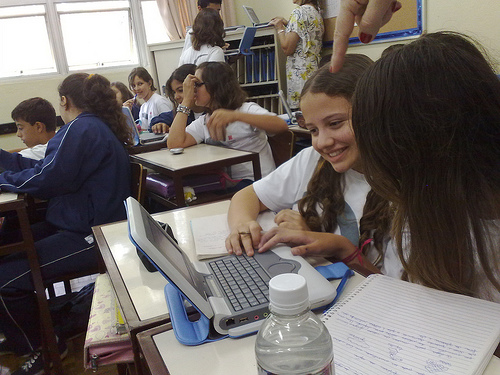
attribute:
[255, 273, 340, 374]
bottle — plastic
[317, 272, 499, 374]
notebook — blue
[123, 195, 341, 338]
laptop — grey, white, small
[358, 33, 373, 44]
fingernails — red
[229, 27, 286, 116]
bookshelf — white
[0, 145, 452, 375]
desks — white, brown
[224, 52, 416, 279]
girl — smiling, sitting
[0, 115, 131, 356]
tracksuit — blue